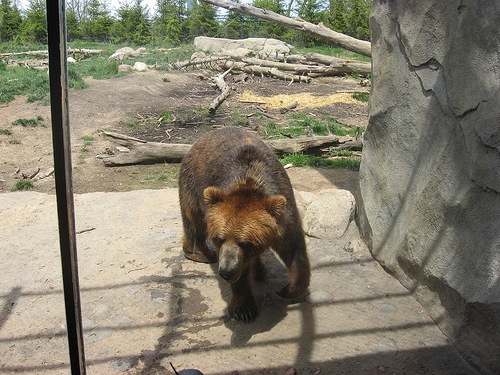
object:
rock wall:
[353, 0, 499, 375]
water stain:
[136, 250, 230, 375]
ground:
[113, 213, 135, 232]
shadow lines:
[318, 264, 395, 331]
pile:
[168, 35, 313, 84]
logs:
[206, 66, 248, 119]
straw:
[280, 100, 298, 113]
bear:
[178, 125, 312, 325]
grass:
[18, 68, 37, 90]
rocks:
[118, 61, 148, 72]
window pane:
[23, 40, 80, 158]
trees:
[115, 5, 276, 45]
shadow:
[210, 247, 312, 346]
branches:
[246, 105, 281, 121]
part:
[13, 207, 41, 234]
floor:
[99, 203, 138, 229]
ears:
[203, 186, 286, 220]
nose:
[218, 267, 234, 279]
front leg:
[268, 213, 312, 299]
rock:
[301, 188, 358, 240]